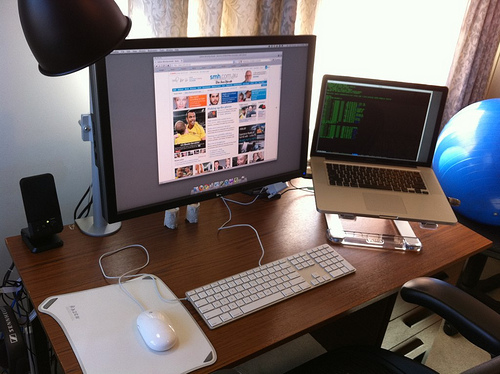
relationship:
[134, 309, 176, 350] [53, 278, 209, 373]
mouse on mouse pad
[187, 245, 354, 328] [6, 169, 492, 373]
keyboard on desk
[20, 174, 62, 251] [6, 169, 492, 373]
speaker on desk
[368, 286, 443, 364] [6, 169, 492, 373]
drawer under desk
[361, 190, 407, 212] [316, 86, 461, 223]
mouse on laptop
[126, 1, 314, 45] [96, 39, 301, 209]
curtains behind monitor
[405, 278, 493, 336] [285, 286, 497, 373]
arm of chair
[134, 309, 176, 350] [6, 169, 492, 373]
mouse on top of desk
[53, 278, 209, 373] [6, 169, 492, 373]
mouse pad on top of desk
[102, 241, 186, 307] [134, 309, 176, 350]
wire connected to mouse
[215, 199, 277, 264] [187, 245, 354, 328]
wire connected to keyboard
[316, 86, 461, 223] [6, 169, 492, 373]
laptop on top of desk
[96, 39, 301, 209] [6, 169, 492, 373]
monitor on desk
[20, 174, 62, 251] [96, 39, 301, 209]
speaker to right of monitor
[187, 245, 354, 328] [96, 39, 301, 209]
keyboard on computer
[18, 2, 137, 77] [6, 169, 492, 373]
lamp over desk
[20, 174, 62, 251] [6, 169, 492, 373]
speaker on top of desk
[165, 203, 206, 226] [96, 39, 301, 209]
support under monitor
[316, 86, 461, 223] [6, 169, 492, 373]
laptop on desk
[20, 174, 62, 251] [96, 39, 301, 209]
speaker near monitor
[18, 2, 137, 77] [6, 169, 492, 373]
lamp above desk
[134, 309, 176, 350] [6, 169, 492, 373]
mouse on desk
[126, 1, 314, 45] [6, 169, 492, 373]
curtains behind desk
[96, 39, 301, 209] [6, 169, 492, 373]
monitor on top of desk